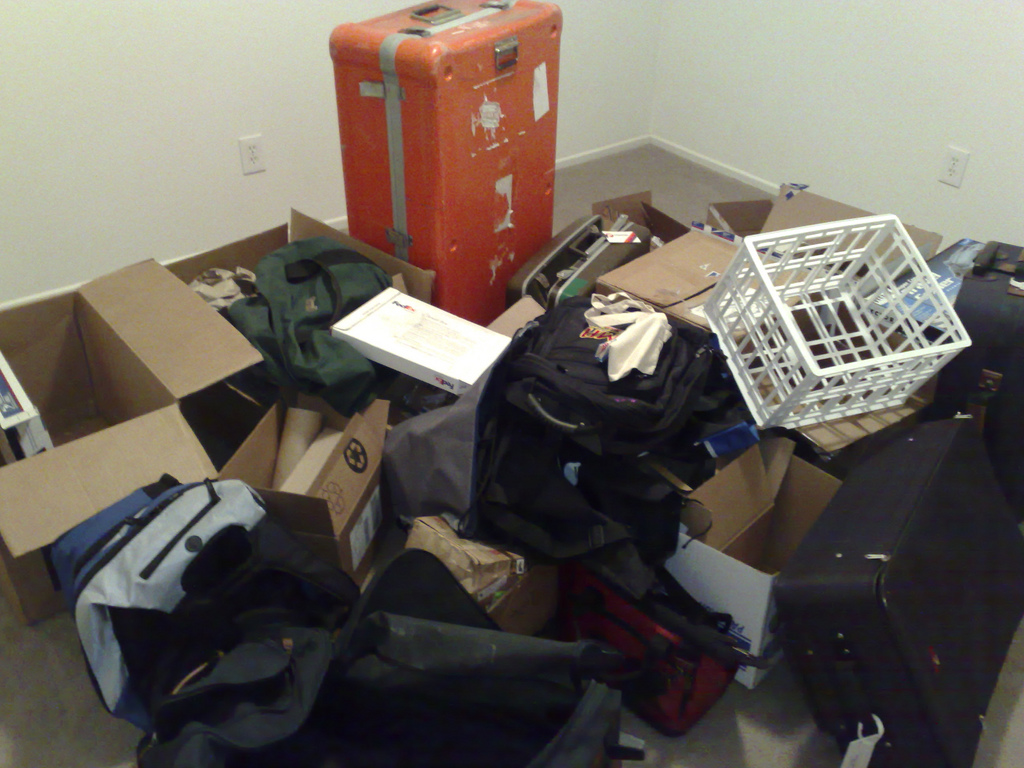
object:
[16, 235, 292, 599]
ground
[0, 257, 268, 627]
box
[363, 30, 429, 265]
stripe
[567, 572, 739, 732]
hand bag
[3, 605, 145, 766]
floor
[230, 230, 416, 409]
bags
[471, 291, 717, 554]
black bag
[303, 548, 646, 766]
bags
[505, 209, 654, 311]
brown suitcase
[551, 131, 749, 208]
floor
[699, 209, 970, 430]
plastic container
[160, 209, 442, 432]
boxes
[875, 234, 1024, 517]
suitcase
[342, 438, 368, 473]
recycle sign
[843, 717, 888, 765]
white tag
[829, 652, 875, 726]
handle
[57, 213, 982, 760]
pile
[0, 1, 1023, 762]
room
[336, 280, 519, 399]
shipping box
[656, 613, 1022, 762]
ground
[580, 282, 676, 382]
paper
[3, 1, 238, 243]
wall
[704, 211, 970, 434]
plastic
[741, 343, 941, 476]
box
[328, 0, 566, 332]
box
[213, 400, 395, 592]
box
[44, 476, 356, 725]
bag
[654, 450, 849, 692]
box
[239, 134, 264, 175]
electrical plug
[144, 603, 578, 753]
bag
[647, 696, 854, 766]
floor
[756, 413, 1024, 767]
bag